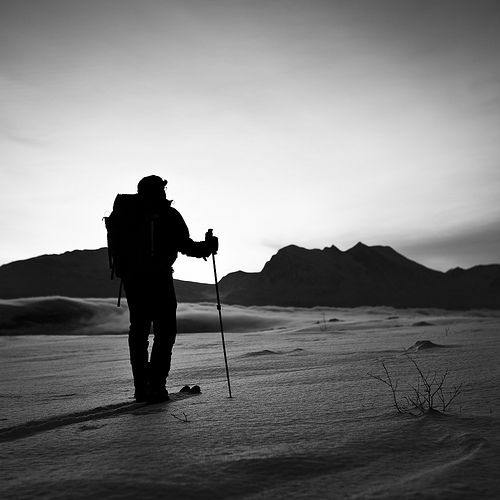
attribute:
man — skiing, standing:
[95, 162, 278, 418]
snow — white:
[32, 275, 364, 493]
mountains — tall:
[27, 227, 464, 313]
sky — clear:
[60, 43, 415, 214]